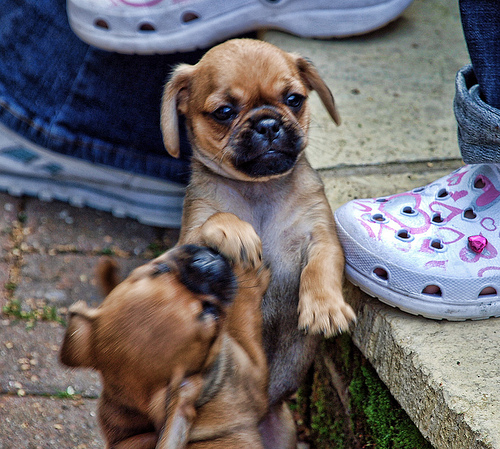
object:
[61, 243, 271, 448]
puppy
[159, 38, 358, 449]
puppy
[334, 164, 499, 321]
croc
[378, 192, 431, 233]
heart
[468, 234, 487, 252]
heart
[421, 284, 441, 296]
hole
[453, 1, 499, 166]
pant-leg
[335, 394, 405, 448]
moss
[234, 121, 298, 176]
muzzle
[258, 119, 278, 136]
nose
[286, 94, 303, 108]
eye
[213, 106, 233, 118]
eye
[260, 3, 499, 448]
step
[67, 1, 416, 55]
shoe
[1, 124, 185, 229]
shoe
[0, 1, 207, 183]
pant-leg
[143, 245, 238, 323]
face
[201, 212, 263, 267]
pawed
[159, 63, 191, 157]
ear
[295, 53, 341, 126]
ear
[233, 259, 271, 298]
claw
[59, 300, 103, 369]
ear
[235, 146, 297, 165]
mouth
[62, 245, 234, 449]
head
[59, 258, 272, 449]
fur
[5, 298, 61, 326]
plants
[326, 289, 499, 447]
slab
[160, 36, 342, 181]
head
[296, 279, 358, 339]
paw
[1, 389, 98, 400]
line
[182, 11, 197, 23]
hole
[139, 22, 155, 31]
hole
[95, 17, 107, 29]
hole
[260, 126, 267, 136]
nostril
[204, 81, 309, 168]
face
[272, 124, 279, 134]
nostril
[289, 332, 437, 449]
side